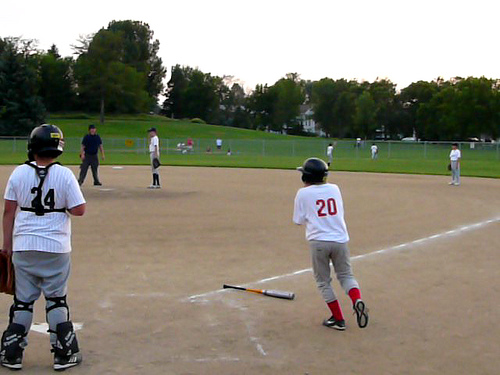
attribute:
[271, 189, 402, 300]
jersey — white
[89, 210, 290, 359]
ground — part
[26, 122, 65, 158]
helmet — black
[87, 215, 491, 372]
lines — white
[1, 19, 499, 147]
leaves — green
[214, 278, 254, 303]
handle — part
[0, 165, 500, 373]
ground — brown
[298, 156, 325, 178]
helmet — black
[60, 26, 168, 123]
tree — green, tall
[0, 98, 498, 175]
grass — trimmed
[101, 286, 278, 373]
groinmd — part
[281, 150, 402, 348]
player — baseball